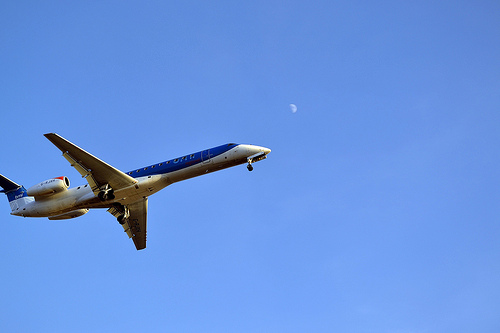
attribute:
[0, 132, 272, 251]
airplane — jet, blue, white, red, flying, displaying logo, taking off, large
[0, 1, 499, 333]
sky — clear, blue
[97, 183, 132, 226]
landing gear — down, black, center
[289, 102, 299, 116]
moon — distant, soft, white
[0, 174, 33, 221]
tail — blue, white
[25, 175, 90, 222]
jets — red, white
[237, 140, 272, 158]
nose — white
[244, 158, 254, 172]
landing gear — black, rubber